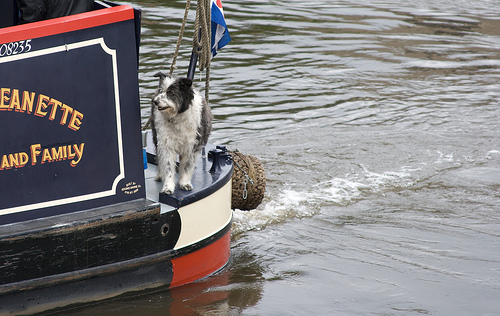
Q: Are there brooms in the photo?
A: No, there are no brooms.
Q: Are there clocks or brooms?
A: No, there are no brooms or clocks.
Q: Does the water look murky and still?
A: Yes, the water is murky and still.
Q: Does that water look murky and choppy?
A: No, the water is murky but still.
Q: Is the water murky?
A: Yes, the water is murky.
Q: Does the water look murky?
A: Yes, the water is murky.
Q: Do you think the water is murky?
A: Yes, the water is murky.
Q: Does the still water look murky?
A: Yes, the water is murky.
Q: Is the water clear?
A: No, the water is murky.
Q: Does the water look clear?
A: No, the water is murky.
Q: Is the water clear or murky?
A: The water is murky.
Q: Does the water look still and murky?
A: Yes, the water is still and murky.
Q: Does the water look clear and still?
A: No, the water is still but murky.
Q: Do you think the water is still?
A: Yes, the water is still.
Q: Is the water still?
A: Yes, the water is still.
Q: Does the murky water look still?
A: Yes, the water is still.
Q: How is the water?
A: The water is still.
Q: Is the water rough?
A: No, the water is still.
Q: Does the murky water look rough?
A: No, the water is still.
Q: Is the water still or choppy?
A: The water is still.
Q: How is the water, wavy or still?
A: The water is still.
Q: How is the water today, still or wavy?
A: The water is still.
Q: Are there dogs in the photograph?
A: Yes, there is a dog.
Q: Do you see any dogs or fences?
A: Yes, there is a dog.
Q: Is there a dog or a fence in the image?
A: Yes, there is a dog.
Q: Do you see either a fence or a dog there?
A: Yes, there is a dog.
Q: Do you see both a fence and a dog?
A: No, there is a dog but no fences.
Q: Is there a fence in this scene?
A: No, there are no fences.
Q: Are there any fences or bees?
A: No, there are no fences or bees.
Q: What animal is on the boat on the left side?
A: The dog is on the boat.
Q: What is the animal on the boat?
A: The animal is a dog.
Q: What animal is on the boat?
A: The animal is a dog.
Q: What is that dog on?
A: The dog is on the boat.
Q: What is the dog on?
A: The dog is on the boat.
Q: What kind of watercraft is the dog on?
A: The dog is on the boat.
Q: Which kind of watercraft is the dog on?
A: The dog is on the boat.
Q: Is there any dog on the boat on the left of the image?
A: Yes, there is a dog on the boat.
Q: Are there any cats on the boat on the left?
A: No, there is a dog on the boat.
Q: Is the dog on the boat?
A: Yes, the dog is on the boat.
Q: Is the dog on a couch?
A: No, the dog is on the boat.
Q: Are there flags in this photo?
A: Yes, there is a flag.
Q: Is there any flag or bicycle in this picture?
A: Yes, there is a flag.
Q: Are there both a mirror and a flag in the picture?
A: No, there is a flag but no mirrors.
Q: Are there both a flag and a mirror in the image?
A: No, there is a flag but no mirrors.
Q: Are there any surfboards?
A: No, there are no surfboards.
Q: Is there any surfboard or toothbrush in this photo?
A: No, there are no surfboards or toothbrushes.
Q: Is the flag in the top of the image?
A: Yes, the flag is in the top of the image.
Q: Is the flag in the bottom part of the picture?
A: No, the flag is in the top of the image.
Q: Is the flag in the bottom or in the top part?
A: The flag is in the top of the image.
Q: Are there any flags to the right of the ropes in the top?
A: Yes, there is a flag to the right of the ropes.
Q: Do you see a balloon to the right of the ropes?
A: No, there is a flag to the right of the ropes.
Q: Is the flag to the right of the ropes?
A: Yes, the flag is to the right of the ropes.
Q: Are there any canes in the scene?
A: No, there are no canes.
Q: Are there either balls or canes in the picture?
A: No, there are no canes or balls.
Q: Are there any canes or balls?
A: No, there are no canes or balls.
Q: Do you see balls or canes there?
A: No, there are no canes or balls.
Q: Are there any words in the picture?
A: Yes, there are words.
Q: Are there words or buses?
A: Yes, there are words.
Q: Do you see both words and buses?
A: No, there are words but no buses.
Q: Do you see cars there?
A: No, there are no cars.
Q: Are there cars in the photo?
A: No, there are no cars.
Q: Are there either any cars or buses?
A: No, there are no cars or buses.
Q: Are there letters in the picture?
A: Yes, there are letters.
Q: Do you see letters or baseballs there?
A: Yes, there are letters.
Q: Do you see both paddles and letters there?
A: No, there are letters but no paddles.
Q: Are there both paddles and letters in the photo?
A: No, there are letters but no paddles.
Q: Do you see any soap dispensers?
A: No, there are no soap dispensers.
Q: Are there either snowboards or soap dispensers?
A: No, there are no soap dispensers or snowboards.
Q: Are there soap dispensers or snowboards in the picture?
A: No, there are no soap dispensers or snowboards.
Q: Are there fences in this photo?
A: No, there are no fences.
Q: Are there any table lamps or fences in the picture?
A: No, there are no fences or table lamps.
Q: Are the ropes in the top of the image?
A: Yes, the ropes are in the top of the image.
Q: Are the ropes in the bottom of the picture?
A: No, the ropes are in the top of the image.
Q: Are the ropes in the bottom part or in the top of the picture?
A: The ropes are in the top of the image.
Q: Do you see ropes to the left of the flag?
A: Yes, there are ropes to the left of the flag.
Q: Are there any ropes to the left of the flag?
A: Yes, there are ropes to the left of the flag.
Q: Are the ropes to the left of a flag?
A: Yes, the ropes are to the left of a flag.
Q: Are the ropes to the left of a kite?
A: No, the ropes are to the left of a flag.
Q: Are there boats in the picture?
A: Yes, there is a boat.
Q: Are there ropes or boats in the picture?
A: Yes, there is a boat.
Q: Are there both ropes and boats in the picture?
A: Yes, there are both a boat and a rope.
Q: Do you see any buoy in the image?
A: No, there are no buoys.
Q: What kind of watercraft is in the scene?
A: The watercraft is a boat.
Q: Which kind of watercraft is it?
A: The watercraft is a boat.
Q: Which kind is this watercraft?
A: This is a boat.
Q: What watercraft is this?
A: This is a boat.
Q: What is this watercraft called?
A: This is a boat.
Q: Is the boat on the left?
A: Yes, the boat is on the left of the image.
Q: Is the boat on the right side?
A: No, the boat is on the left of the image.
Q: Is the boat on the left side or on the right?
A: The boat is on the left of the image.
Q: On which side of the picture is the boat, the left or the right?
A: The boat is on the left of the image.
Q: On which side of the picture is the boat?
A: The boat is on the left of the image.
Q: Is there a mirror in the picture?
A: No, there are no mirrors.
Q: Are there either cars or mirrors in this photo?
A: No, there are no mirrors or cars.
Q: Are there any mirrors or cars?
A: No, there are no mirrors or cars.